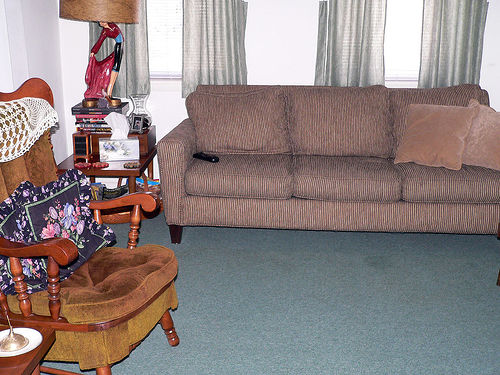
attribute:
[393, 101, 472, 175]
pillows — brown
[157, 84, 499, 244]
sofa — brown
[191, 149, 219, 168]
remote — black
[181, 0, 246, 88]
drapes — grey, gray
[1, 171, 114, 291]
pillows — blue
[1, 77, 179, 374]
chair — brown, wooden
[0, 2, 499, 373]
living room — small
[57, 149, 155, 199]
end table — small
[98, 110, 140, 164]
tissues — white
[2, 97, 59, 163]
doily — white, knitted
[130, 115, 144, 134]
picture — framed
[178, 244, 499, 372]
carpet — gray, carpeted